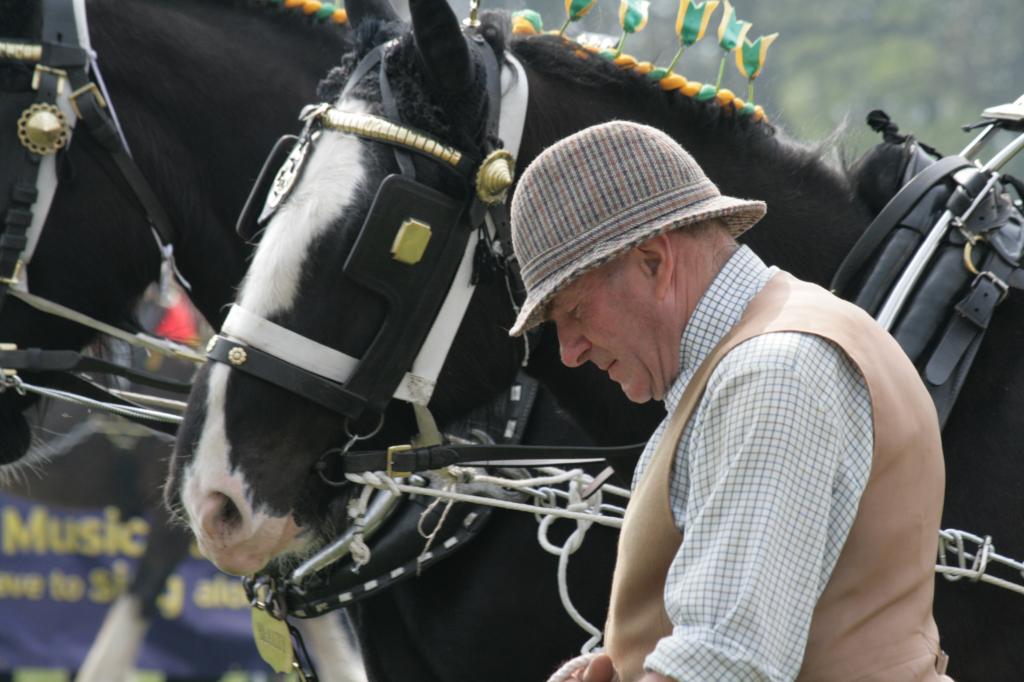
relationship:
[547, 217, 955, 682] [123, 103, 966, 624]
man are enjoying outdoors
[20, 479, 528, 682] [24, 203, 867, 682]
people are enjoying outdoors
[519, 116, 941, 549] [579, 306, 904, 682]
person standing up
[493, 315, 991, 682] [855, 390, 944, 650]
man in a checkered shirt and brown vest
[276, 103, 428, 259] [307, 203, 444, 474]
horse with a bridle and eye covers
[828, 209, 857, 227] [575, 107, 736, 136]
green and yellow braided horses mane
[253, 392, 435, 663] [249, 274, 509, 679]
mouth bit of horse bridle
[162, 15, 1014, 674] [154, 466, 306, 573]
horse has muzzle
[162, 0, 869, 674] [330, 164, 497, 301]
horse wears blinders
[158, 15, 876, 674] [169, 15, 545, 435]
horse wears harness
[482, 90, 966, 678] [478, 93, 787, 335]
man wears hat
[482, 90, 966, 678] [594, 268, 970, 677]
man wears vest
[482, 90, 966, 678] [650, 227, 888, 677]
man wears shirt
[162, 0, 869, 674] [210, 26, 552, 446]
horse has harness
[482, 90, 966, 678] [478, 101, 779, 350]
man wears hat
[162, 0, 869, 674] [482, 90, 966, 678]
horse next man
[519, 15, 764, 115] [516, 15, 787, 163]
ribon on mane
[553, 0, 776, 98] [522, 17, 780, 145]
flags sticking out of ribbon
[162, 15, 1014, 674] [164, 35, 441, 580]
horse has face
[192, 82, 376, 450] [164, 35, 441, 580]
mark on face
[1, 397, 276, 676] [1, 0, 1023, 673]
banner behind horses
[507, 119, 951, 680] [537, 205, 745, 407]
man has head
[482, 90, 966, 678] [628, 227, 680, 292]
man has ear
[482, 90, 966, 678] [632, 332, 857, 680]
man has arm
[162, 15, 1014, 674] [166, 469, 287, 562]
horse has nose